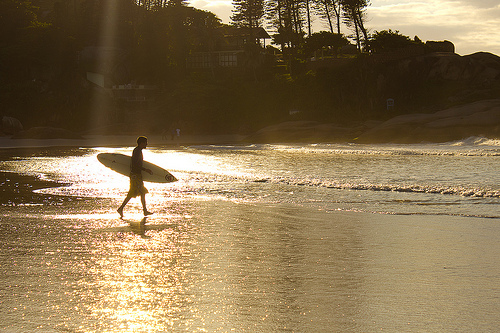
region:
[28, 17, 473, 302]
person walking towards water with surfboard.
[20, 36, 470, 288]
surfer walking towards water with surfboard.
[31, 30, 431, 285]
person walking on beach with surfboard.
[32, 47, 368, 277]
surfer walking on beach with surfboard.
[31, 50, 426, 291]
person walking towards waves with surfboard.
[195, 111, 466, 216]
some beautiful water waves.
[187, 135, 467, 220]
some attractive water waves.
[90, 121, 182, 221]
person outside with surfboard.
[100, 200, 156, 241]
feet walking on beach.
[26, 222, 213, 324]
sunlight glistening on beautiful beach.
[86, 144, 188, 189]
surf board is white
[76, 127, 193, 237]
man is holding a surfboard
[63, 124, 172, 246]
Man carrying a surfboard.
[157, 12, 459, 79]
House on a hill near a beach.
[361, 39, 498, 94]
Rocky outcropping near a beach.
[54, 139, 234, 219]
Reflection of the sun in shallow water.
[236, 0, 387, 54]
Trees on a hill.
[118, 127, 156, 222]
Man wearing yellow shorts.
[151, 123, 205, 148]
Three people on a beach.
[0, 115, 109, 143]
Large rocks on a beach.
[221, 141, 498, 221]
Small waves in shallow water.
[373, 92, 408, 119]
Small sign on a hill.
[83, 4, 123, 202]
a ray of sunshine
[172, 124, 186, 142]
a person in a white shirt in the distance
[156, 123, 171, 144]
two other people in the distance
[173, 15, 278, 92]
a house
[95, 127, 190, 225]
a surfer going into the waves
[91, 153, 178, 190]
a surfboard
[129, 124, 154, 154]
a person's head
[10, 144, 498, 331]
the water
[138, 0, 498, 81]
the sky at sunset or sunrise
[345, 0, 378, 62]
a tall tree